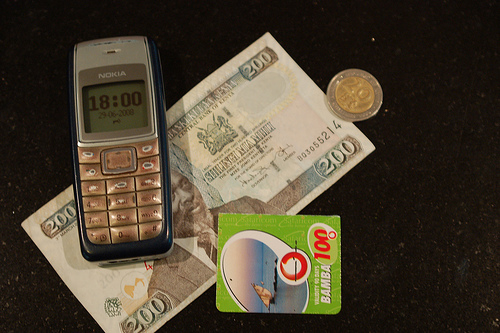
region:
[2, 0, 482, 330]
a black table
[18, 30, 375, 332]
a piece of paper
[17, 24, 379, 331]
a single paper currency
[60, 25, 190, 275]
a cell phone that is gray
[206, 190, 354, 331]
a green card BAMBA 100 written on it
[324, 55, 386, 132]
a gold coin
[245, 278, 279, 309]
an image of sailboat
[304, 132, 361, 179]
the number 200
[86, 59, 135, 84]
the phone that has NOKIA written on it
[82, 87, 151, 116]
a cell phone that 18:00 on it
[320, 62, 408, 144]
The coin is two tone.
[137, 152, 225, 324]
The money has a man's picture.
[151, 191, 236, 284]
The man is wearing a tie.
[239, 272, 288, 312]
The sail boat is in the water.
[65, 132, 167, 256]
Multiple buttons appear copper colored.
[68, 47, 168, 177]
The time is shown in military time.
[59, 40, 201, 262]
The phone is on.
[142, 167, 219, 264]
The man has a gray beard.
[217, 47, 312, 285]
Paper money lays under the green card.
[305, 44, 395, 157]
Coin money is on top of paper money.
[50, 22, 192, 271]
A cell phone.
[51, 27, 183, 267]
The cell phone is large.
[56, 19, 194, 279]
The cell phone has buttons.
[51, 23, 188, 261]
The cell phone is gray and black.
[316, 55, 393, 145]
A coin.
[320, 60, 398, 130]
The coin is made of metal.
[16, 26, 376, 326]
A paper note.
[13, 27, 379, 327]
The note is mostly white.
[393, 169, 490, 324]
The surface is black.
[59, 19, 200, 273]
The phone is showing the time.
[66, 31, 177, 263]
an old Nokia phone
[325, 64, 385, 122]
a coin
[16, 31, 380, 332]
a 200 note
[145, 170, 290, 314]
a man in a suit on the bill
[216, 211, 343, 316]
a green card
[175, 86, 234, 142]
the words Central Bank of Kenya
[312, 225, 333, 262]
the number 100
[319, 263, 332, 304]
the word Bamba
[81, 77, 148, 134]
the screen of the phone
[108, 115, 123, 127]
a key on the phone's screen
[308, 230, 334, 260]
I00 ON THE CARD IN RED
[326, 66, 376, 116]
COIN IS LAYING ON THE 200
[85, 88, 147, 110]
TIME ON THE PHONE IS 18:00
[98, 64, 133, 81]
NAME ON THE PHONE IS NOKIA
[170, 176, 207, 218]
MAN IS ON THE FRONT OF THE BILL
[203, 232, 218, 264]
MAN IS WEARING A TIE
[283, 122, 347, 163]
BLACK NUMBERS IS IN THE BOTTOM RIGHT CORNER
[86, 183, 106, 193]
NUMBERS HAVE FADED OFF THE BUTTONS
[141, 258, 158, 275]
RED 4 IS ON THE BILL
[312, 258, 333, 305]
WORDS IN WHITE BAMBA ON THE CARD